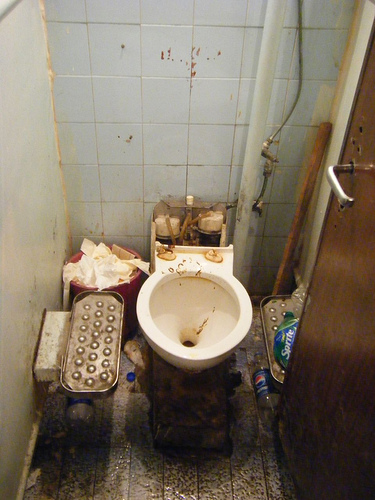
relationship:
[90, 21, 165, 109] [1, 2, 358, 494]
wall on side of a building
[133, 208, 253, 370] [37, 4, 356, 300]
toilet attached to wall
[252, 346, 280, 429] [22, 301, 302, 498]
pepsi bottle on ground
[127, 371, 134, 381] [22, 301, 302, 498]
bottle top on ground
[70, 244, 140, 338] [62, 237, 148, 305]
trashcan filled with trash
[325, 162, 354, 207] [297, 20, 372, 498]
handle on door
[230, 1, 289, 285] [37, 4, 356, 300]
pipe against wall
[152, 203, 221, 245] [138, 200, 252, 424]
inside of toilet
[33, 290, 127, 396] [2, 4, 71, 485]
stand attached to wall